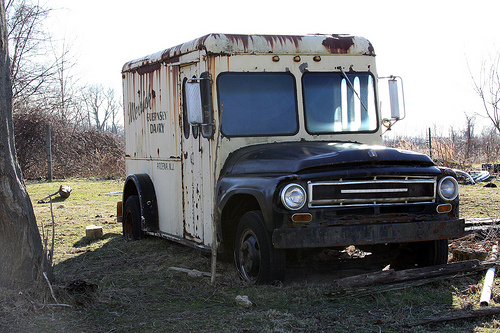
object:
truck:
[116, 33, 465, 286]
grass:
[0, 179, 499, 333]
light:
[281, 182, 306, 211]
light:
[437, 175, 459, 201]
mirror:
[387, 75, 407, 122]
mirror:
[183, 78, 203, 127]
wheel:
[121, 197, 141, 242]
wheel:
[231, 210, 284, 286]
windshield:
[215, 70, 379, 138]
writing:
[127, 89, 168, 133]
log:
[322, 257, 499, 304]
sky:
[1, 0, 500, 142]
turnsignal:
[289, 212, 311, 223]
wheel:
[414, 238, 448, 266]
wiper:
[336, 67, 367, 111]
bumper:
[272, 218, 464, 247]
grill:
[306, 173, 436, 208]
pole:
[47, 123, 54, 184]